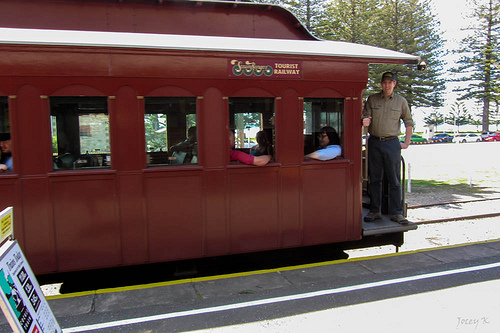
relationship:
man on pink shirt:
[227, 131, 276, 167] [229, 148, 254, 165]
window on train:
[0, 94, 15, 179] [0, 0, 428, 289]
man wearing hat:
[361, 69, 415, 226] [379, 64, 404, 103]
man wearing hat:
[339, 62, 440, 267] [358, 54, 434, 99]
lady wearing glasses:
[301, 122, 342, 164] [302, 118, 342, 164]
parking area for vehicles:
[388, 127, 498, 152] [391, 122, 498, 139]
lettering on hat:
[384, 70, 394, 77] [376, 67, 400, 80]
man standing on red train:
[361, 69, 415, 226] [5, 0, 419, 284]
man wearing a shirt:
[361, 69, 415, 226] [358, 80, 422, 137]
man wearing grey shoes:
[361, 69, 415, 226] [364, 207, 413, 232]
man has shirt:
[227, 133, 270, 165] [215, 149, 256, 161]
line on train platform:
[28, 200, 498, 256] [72, 264, 474, 331]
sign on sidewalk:
[0, 239, 65, 331] [97, 284, 251, 331]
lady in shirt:
[304, 125, 341, 163] [315, 145, 338, 157]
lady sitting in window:
[304, 125, 341, 163] [304, 97, 344, 159]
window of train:
[304, 97, 344, 159] [0, 0, 428, 289]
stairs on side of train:
[362, 176, 389, 216] [0, 0, 428, 289]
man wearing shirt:
[361, 69, 415, 226] [363, 90, 412, 139]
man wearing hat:
[361, 69, 415, 226] [374, 67, 410, 83]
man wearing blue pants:
[361, 69, 415, 226] [365, 132, 406, 222]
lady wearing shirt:
[304, 125, 341, 163] [316, 142, 341, 161]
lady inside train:
[304, 125, 341, 163] [0, 0, 428, 289]